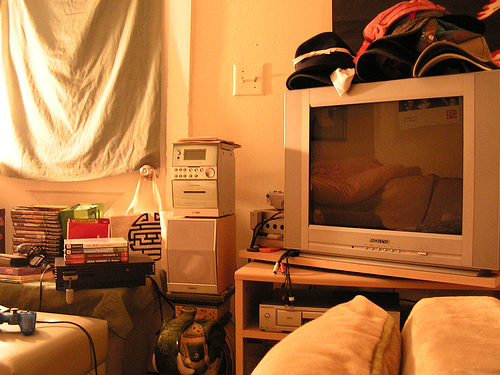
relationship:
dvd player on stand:
[260, 288, 329, 336] [232, 247, 363, 375]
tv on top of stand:
[283, 68, 499, 278] [232, 247, 363, 375]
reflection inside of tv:
[312, 157, 461, 231] [283, 68, 499, 278]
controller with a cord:
[1, 306, 37, 336] [34, 316, 74, 328]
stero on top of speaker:
[171, 143, 237, 216] [169, 220, 238, 293]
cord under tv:
[271, 247, 299, 312] [283, 68, 499, 278]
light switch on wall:
[235, 64, 265, 94] [163, 0, 285, 207]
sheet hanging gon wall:
[1, 1, 161, 182] [163, 0, 285, 207]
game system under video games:
[54, 259, 152, 288] [65, 240, 127, 263]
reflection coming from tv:
[312, 157, 461, 231] [283, 68, 499, 278]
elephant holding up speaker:
[153, 289, 232, 373] [169, 220, 238, 293]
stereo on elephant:
[171, 143, 237, 216] [153, 289, 232, 373]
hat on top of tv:
[360, 1, 444, 43] [283, 68, 499, 278]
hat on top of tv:
[357, 44, 412, 79] [283, 68, 499, 278]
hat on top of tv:
[408, 31, 493, 77] [283, 68, 499, 278]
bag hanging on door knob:
[106, 177, 172, 261] [140, 163, 161, 182]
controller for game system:
[1, 306, 37, 336] [54, 259, 152, 288]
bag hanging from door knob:
[106, 177, 172, 261] [140, 163, 161, 182]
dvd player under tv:
[260, 288, 329, 336] [283, 68, 499, 278]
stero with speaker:
[171, 143, 237, 216] [169, 220, 238, 293]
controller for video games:
[1, 306, 37, 336] [12, 205, 60, 254]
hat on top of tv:
[382, 8, 441, 36] [283, 68, 499, 278]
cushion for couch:
[250, 294, 403, 375] [241, 297, 499, 375]